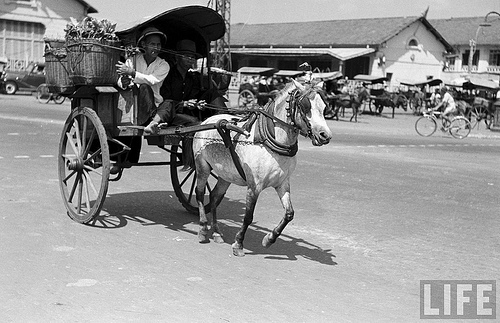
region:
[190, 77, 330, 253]
White horse pulling a carriage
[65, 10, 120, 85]
Basket of goods that look like plants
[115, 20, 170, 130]
Man in a hat and white shirt but without shoes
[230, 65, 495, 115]
A row of horse carriages in the background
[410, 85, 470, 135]
A person riding a bicycle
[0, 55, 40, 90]
Front half of an automobile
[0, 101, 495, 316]
Paved road for traffic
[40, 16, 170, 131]
Man holding two baskets of goods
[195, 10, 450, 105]
Two storey building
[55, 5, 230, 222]
Carriage with two wheels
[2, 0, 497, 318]
a black and white magazine image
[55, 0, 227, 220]
two men riding in a wheeled cart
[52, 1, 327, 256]
horse pulling cart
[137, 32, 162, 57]
cigarette-like object in man's mouth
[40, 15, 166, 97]
man's hand steadying one of two large baskets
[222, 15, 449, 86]
a long building with a long awning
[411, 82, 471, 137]
person on a bicycle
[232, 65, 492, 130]
covered carts and horses in the background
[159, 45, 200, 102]
man wearing a dark buttoned shirt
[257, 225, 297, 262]
horse's hoof is off the ground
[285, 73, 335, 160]
Head of the horse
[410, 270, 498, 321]
LIFE tag on the image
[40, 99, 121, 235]
Right wheel of carriage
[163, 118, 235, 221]
Left wheel of carriage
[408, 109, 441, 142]
Front wheel of bicycle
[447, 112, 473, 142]
Back wheel of bicycle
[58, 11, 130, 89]
Basket full of plants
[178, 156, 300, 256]
Legs of the horse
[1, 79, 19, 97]
Front tire of car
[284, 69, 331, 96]
Ears of the horse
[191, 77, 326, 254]
a trotting horse pulling a wagon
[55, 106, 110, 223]
a wooden wagon wheel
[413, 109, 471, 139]
a bike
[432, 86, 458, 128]
a man riding a bike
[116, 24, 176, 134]
a man riding in a wooden wagon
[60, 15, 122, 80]
a whisker basket filled with vegetation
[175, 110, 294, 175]
a harness on a horse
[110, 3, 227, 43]
a roof on a wooden wagon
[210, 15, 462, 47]
a roof on a building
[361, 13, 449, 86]
a white building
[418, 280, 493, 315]
life lettering in the lower right corner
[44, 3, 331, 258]
horse pulling a carriage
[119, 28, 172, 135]
man in a horse carriage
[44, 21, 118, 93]
basket of produce on the carriage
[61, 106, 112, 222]
large wheel on the horse carriage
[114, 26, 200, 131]
two men sitting in the carriage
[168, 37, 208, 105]
man in black steering the carriage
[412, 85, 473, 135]
person riding a bike in the background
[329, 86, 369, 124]
horse in the background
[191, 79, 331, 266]
white horse pulling a carriage